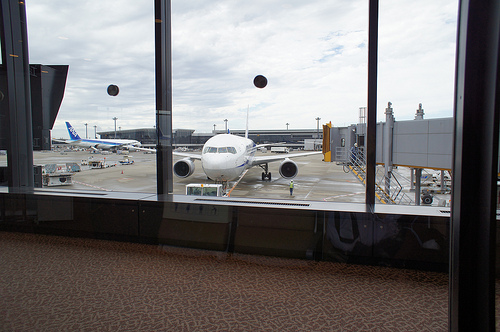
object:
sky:
[21, 0, 457, 127]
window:
[225, 146, 237, 153]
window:
[217, 146, 225, 153]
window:
[204, 147, 216, 152]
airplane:
[53, 121, 143, 153]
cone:
[121, 170, 125, 174]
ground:
[34, 141, 451, 204]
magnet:
[106, 84, 119, 96]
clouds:
[17, 1, 463, 98]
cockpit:
[201, 143, 238, 156]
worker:
[351, 143, 359, 163]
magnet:
[0, 0, 35, 189]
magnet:
[254, 75, 267, 89]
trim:
[322, 123, 332, 162]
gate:
[321, 103, 454, 208]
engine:
[173, 158, 195, 179]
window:
[0, 94, 6, 192]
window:
[375, 0, 463, 216]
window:
[166, 0, 367, 208]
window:
[14, 0, 162, 195]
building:
[96, 128, 324, 151]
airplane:
[126, 133, 322, 182]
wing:
[128, 145, 201, 161]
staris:
[335, 146, 416, 206]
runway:
[83, 139, 202, 192]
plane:
[173, 133, 325, 183]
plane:
[50, 121, 142, 155]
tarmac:
[9, 120, 452, 208]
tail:
[50, 121, 82, 146]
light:
[0, 63, 70, 149]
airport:
[0, 0, 454, 207]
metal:
[154, 0, 172, 194]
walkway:
[323, 102, 457, 207]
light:
[111, 116, 118, 138]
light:
[83, 123, 88, 139]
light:
[93, 125, 97, 138]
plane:
[128, 134, 325, 188]